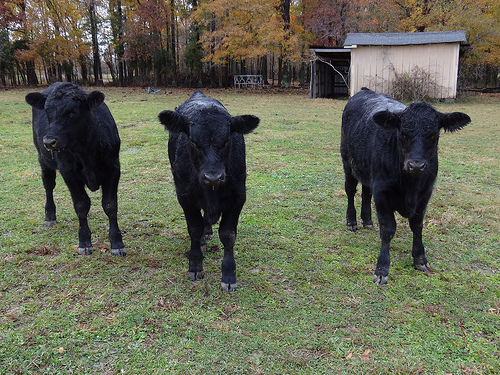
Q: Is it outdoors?
A: Yes, it is outdoors.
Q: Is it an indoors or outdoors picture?
A: It is outdoors.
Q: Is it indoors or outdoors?
A: It is outdoors.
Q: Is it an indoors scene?
A: No, it is outdoors.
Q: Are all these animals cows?
A: Yes, all the animals are cows.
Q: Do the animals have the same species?
A: Yes, all the animals are cows.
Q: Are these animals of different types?
A: No, all the animals are cows.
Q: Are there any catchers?
A: No, there are no catchers.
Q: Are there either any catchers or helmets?
A: No, there are no catchers or helmets.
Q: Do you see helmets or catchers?
A: No, there are no catchers or helmets.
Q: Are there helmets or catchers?
A: No, there are no catchers or helmets.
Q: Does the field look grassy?
A: Yes, the field is grassy.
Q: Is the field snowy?
A: No, the field is grassy.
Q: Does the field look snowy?
A: No, the field is grassy.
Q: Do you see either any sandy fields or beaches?
A: No, there is a field but it is grassy.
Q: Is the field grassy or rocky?
A: The field is grassy.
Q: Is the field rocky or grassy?
A: The field is grassy.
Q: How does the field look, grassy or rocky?
A: The field is grassy.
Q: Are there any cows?
A: Yes, there are cows.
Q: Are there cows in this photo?
A: Yes, there are cows.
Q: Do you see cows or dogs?
A: Yes, there are cows.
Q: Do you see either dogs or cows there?
A: Yes, there are cows.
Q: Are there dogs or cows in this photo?
A: Yes, there are cows.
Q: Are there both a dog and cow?
A: No, there are cows but no dogs.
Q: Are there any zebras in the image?
A: No, there are no zebras.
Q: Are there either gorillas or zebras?
A: No, there are no zebras or gorillas.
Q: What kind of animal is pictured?
A: The animal is cows.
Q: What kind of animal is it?
A: The animals are cows.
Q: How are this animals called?
A: These are cows.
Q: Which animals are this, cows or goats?
A: These are cows.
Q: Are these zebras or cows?
A: These are cows.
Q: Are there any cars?
A: No, there are no cars.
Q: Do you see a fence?
A: Yes, there is a fence.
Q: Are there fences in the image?
A: Yes, there is a fence.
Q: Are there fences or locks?
A: Yes, there is a fence.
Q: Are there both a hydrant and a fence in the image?
A: No, there is a fence but no fire hydrants.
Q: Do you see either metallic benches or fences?
A: Yes, there is a metal fence.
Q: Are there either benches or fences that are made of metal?
A: Yes, the fence is made of metal.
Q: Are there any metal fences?
A: Yes, there is a metal fence.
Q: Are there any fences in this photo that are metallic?
A: Yes, there is a fence that is metallic.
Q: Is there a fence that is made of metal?
A: Yes, there is a fence that is made of metal.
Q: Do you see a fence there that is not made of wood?
A: Yes, there is a fence that is made of metal.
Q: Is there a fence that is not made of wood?
A: Yes, there is a fence that is made of metal.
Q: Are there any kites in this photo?
A: No, there are no kites.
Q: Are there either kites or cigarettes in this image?
A: No, there are no kites or cigarettes.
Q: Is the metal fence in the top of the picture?
A: Yes, the fence is in the top of the image.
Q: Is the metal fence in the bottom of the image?
A: No, the fence is in the top of the image.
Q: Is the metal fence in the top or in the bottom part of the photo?
A: The fence is in the top of the image.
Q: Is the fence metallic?
A: Yes, the fence is metallic.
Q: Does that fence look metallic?
A: Yes, the fence is metallic.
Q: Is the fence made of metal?
A: Yes, the fence is made of metal.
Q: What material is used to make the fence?
A: The fence is made of metal.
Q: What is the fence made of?
A: The fence is made of metal.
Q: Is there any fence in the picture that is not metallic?
A: No, there is a fence but it is metallic.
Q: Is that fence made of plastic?
A: No, the fence is made of metal.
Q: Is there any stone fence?
A: No, there is a fence but it is made of metal.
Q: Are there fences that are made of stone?
A: No, there is a fence but it is made of metal.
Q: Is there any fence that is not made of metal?
A: No, there is a fence but it is made of metal.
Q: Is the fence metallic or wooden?
A: The fence is metallic.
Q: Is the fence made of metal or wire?
A: The fence is made of metal.